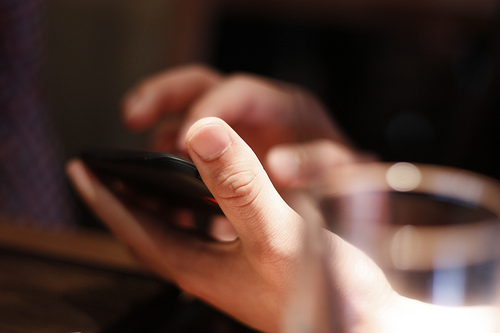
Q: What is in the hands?
A: Phone.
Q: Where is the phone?
A: In the hands.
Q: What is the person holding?
A: A phone.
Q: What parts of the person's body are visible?
A: Left and right hands.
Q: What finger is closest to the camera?
A: Left hand thumb.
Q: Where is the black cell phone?
A: In the person's left hand.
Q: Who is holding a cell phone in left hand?
A: A person.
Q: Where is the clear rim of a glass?
A: Between the hands.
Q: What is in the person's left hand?
A: Black cell phone.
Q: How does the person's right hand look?
A: Blurry.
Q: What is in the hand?
A: Cell phone.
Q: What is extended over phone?
A: Thumb.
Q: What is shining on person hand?
A: Light.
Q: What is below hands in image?
A: Brown surface.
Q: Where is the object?
A: In foreground.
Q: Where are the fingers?
A: On person's hand.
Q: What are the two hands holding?
A: A phone.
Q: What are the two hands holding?
A: A phone.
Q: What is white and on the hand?
A: The thumb finger.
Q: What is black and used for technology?
A: The phone.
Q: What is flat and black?
A: The phone.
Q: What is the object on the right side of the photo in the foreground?
A: Drinking glass.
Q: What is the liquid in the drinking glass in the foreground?
A: None.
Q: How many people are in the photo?
A: One.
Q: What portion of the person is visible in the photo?
A: Hands.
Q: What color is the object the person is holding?
A: Black.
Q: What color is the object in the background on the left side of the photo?
A: Purple.